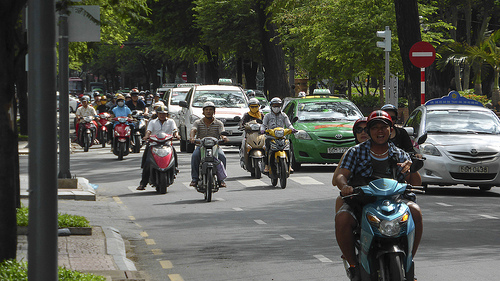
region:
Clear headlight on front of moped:
[380, 218, 402, 235]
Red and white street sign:
[408, 43, 435, 105]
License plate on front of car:
[458, 163, 491, 173]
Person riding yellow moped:
[261, 95, 296, 187]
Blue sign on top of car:
[425, 89, 484, 106]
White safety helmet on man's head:
[201, 100, 216, 109]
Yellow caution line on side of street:
[111, 191, 182, 278]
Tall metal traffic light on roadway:
[376, 26, 392, 102]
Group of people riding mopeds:
[76, 88, 146, 158]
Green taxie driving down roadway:
[283, 88, 364, 168]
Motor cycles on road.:
[99, 88, 401, 258]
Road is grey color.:
[178, 208, 305, 271]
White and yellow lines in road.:
[109, 125, 372, 272]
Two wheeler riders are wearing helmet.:
[77, 78, 387, 233]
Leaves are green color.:
[163, 2, 329, 45]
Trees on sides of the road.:
[148, 18, 355, 84]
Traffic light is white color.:
[356, 28, 397, 90]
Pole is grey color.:
[13, 33, 85, 224]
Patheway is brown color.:
[63, 231, 105, 268]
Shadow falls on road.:
[86, 123, 398, 279]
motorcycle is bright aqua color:
[356, 181, 413, 242]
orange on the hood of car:
[320, 114, 369, 135]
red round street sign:
[405, 37, 449, 73]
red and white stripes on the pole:
[413, 64, 436, 110]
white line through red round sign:
[414, 40, 435, 57]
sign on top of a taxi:
[311, 82, 333, 93]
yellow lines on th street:
[144, 213, 173, 275]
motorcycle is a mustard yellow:
[271, 123, 292, 165]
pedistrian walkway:
[166, 166, 297, 186]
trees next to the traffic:
[326, 13, 367, 61]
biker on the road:
[263, 93, 304, 187]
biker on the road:
[338, 120, 429, 271]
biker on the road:
[196, 108, 231, 200]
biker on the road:
[138, 98, 194, 190]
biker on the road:
[113, 96, 142, 158]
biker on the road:
[134, 93, 145, 136]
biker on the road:
[74, 95, 101, 151]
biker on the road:
[96, 92, 109, 138]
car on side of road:
[403, 88, 495, 191]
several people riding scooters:
[60, 81, 302, 213]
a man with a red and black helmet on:
[365, 111, 396, 145]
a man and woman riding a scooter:
[338, 108, 417, 279]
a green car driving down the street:
[276, 89, 371, 176]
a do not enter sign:
[403, 35, 443, 99]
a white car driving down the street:
[405, 85, 499, 215]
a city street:
[125, 202, 338, 279]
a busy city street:
[63, 48, 498, 265]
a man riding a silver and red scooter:
[141, 102, 183, 194]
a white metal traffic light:
[370, 23, 403, 113]